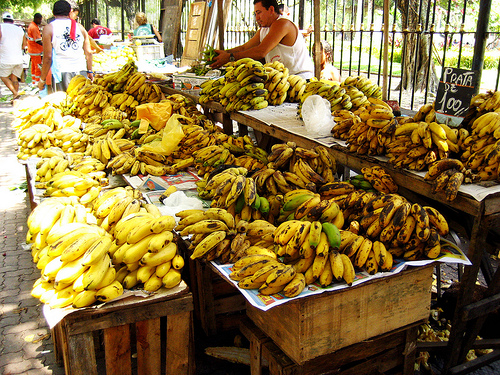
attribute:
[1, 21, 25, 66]
shirt — white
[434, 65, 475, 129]
sign — black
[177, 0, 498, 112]
fence — metal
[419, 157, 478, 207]
bananas — black, hanging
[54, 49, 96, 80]
sign — black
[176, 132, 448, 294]
bananas — overripe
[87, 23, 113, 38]
shirt — red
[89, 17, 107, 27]
hat — black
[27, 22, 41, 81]
clothes — orange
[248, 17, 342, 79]
shirt — orange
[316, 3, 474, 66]
poles — black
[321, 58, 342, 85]
shirt — white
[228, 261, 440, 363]
crate — wooden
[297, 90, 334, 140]
bag — plastic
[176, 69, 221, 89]
cardboard — box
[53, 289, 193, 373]
crate boards — wood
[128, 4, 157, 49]
woman — in blue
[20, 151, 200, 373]
table — ripe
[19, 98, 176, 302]
bananas — yellow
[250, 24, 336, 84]
shirt — white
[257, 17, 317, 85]
shirt — white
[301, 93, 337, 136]
bag — empty, clear, plastic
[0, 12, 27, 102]
man — walking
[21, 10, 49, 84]
man — in orange, looking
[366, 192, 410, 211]
skin — over ripe, dark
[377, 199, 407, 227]
skin — dark, over ripe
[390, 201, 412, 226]
skin — dark, over ripe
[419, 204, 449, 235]
skin — dark, over ripe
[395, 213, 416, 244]
skin — dark, over ripe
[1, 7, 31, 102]
people — walking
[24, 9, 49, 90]
people — walking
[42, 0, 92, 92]
people — walking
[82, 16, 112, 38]
people — walking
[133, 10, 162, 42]
people — walking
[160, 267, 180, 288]
plantain — yellow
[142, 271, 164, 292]
plantain — yellow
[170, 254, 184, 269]
plantain — yellow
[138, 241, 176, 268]
plantain — yellow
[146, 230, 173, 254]
plantain — yellow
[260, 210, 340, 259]
banana — green, unripe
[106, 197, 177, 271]
banana — green, unripe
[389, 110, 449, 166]
banana — green, unripe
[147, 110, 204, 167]
banana — green, unripe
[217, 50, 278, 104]
banana — green, unripe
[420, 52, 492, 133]
sign — black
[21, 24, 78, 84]
shirt — red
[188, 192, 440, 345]
tables — wood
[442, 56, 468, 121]
numbers — white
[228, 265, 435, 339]
box — wood